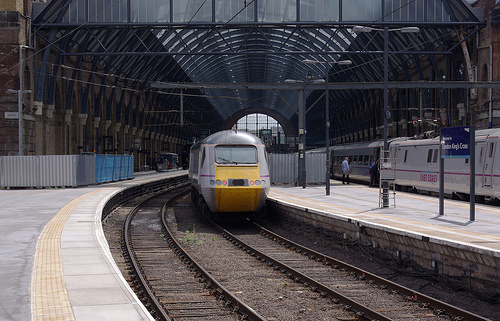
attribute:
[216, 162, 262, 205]
front — yellow, glass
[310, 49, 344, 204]
pole — straight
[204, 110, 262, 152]
top — metallic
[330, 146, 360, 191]
man — standing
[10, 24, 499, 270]
scene — subway, shed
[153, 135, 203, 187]
people — boarding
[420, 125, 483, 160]
sign — blue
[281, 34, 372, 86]
lamp — off, street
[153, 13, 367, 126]
roof — dome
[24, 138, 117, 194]
wall — brick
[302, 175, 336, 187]
grass — growing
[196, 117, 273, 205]
train — yellow, brown, white, silver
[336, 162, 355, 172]
shirt — blue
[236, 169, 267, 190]
light — head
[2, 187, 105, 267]
area — concrete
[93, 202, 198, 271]
track — railway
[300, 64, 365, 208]
post — lamp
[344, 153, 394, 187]
bin — blue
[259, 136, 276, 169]
mirror — silver